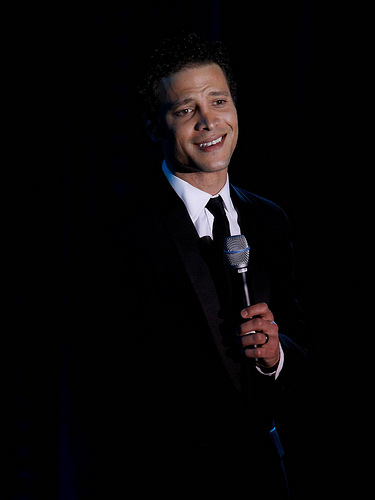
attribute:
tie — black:
[204, 192, 233, 248]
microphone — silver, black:
[216, 263, 272, 302]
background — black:
[0, 1, 373, 499]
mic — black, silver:
[215, 230, 285, 361]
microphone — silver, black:
[221, 231, 264, 371]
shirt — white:
[161, 158, 238, 242]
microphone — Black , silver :
[194, 231, 303, 366]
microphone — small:
[223, 233, 258, 362]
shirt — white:
[175, 184, 243, 239]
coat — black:
[91, 163, 341, 490]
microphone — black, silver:
[215, 212, 264, 313]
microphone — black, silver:
[226, 236, 252, 302]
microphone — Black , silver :
[221, 232, 286, 461]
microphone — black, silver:
[222, 237, 272, 365]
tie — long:
[182, 182, 260, 295]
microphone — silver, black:
[222, 229, 260, 364]